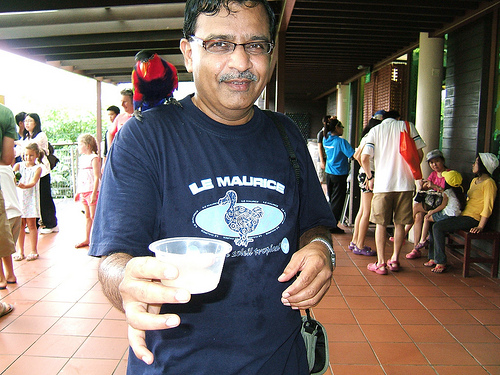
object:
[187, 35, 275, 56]
glasses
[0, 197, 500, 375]
red pavement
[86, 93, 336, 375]
blue shirt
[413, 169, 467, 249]
person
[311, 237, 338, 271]
watch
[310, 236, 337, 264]
wrist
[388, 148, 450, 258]
person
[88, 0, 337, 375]
man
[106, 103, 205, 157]
shoulder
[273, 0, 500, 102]
ceiling beams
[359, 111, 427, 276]
people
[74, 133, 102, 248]
person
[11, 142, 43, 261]
person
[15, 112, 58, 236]
person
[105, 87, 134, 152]
person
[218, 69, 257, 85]
moustache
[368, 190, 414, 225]
shorts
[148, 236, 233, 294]
container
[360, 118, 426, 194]
shirt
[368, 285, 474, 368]
floor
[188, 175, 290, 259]
white graphic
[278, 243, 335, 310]
hand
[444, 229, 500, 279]
bench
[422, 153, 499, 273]
people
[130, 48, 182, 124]
bird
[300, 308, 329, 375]
bag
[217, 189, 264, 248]
duck image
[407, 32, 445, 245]
column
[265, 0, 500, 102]
ceiling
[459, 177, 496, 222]
shirt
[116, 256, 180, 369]
hand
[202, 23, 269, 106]
face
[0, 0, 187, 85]
beams